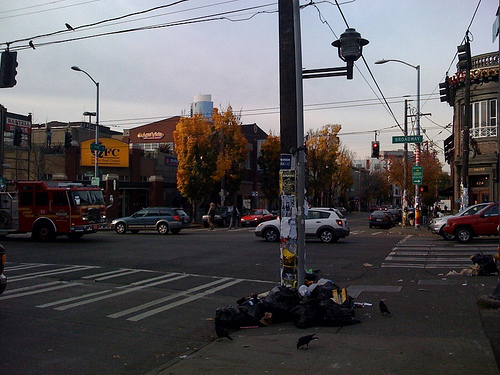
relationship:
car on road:
[109, 203, 191, 240] [0, 216, 498, 283]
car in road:
[109, 207, 192, 235] [7, 227, 263, 373]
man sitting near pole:
[298, 272, 360, 324] [275, 2, 303, 294]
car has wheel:
[251, 205, 351, 242] [318, 223, 335, 245]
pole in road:
[286, 3, 308, 318] [7, 221, 497, 365]